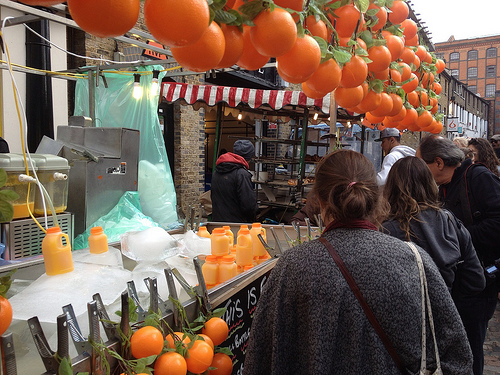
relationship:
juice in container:
[7, 188, 35, 221] [1, 150, 33, 225]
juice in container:
[34, 197, 68, 216] [26, 150, 71, 220]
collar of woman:
[317, 214, 379, 235] [271, 149, 474, 371]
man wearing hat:
[223, 130, 255, 200] [230, 137, 256, 154]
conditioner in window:
[45, 17, 208, 117] [1, 29, 97, 174]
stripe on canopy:
[181, 78, 245, 107] [153, 67, 340, 133]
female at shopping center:
[242, 149, 476, 375] [11, 15, 456, 342]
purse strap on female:
[318, 234, 421, 374] [242, 149, 476, 375]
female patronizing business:
[242, 149, 476, 375] [0, 12, 333, 372]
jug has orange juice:
[212, 220, 253, 256] [211, 231, 232, 260]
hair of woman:
[310, 175, 380, 222] [209, 165, 469, 363]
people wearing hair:
[379, 155, 486, 297] [384, 155, 446, 241]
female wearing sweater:
[242, 149, 476, 375] [239, 227, 473, 372]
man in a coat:
[210, 139, 259, 224] [216, 159, 258, 221]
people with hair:
[379, 155, 486, 297] [387, 154, 442, 228]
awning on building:
[160, 77, 340, 116] [85, 0, 297, 222]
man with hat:
[210, 139, 259, 224] [228, 127, 263, 163]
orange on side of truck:
[251, 5, 297, 57] [40, 144, 278, 343]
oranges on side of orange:
[277, 25, 323, 85] [251, 5, 297, 57]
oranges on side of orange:
[196, 303, 231, 346] [251, 5, 297, 57]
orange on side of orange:
[129, 325, 165, 360] [251, 5, 297, 57]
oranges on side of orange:
[143, 0, 213, 46] [251, 5, 297, 57]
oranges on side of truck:
[66, 2, 453, 147] [3, 3, 499, 367]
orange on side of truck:
[251, 5, 297, 55] [1, 2, 435, 374]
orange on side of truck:
[279, 34, 320, 76] [1, 2, 435, 374]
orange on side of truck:
[143, 0, 207, 46] [1, 2, 435, 374]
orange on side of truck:
[205, 317, 227, 343] [1, 2, 435, 374]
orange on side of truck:
[131, 322, 163, 359] [1, 2, 435, 374]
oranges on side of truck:
[359, 0, 419, 127] [94, 21, 403, 187]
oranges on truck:
[85, 0, 452, 132] [1, 199, 331, 368]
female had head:
[242, 149, 476, 375] [303, 144, 374, 226]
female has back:
[242, 149, 476, 375] [287, 257, 368, 367]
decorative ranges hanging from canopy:
[86, 2, 463, 148] [159, 58, 352, 125]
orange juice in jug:
[40, 225, 72, 277] [42, 242, 73, 282]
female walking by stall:
[242, 149, 476, 375] [1, 0, 445, 374]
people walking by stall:
[379, 155, 486, 297] [1, 0, 445, 374]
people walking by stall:
[413, 134, 497, 374] [1, 0, 445, 374]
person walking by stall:
[465, 134, 499, 179] [1, 0, 445, 374]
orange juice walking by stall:
[38, 225, 76, 277] [1, 0, 445, 374]